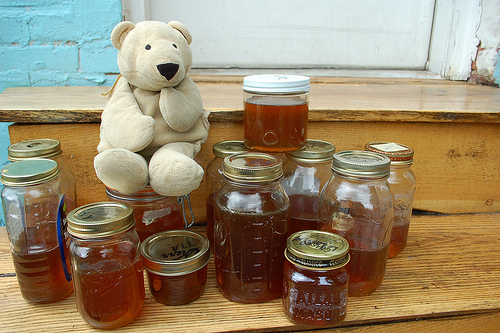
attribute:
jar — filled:
[279, 228, 349, 325]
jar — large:
[210, 150, 290, 302]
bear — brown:
[97, 15, 209, 193]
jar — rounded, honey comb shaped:
[1, 156, 73, 304]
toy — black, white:
[89, 17, 214, 201]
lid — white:
[243, 72, 313, 97]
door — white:
[195, 7, 438, 69]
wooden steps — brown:
[220, 61, 498, 243]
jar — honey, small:
[142, 224, 212, 304]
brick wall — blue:
[3, 2, 129, 104]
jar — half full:
[325, 147, 411, 273]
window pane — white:
[208, 29, 428, 69]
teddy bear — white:
[103, 20, 213, 195]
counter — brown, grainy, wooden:
[43, 105, 495, 296]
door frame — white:
[448, 0, 497, 74]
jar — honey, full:
[216, 152, 286, 303]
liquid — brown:
[391, 225, 407, 252]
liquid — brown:
[348, 250, 385, 294]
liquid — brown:
[218, 212, 285, 299]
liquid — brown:
[244, 97, 308, 149]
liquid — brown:
[76, 250, 141, 324]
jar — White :
[236, 69, 316, 162]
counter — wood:
[1, 209, 499, 327]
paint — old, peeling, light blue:
[3, 0, 123, 176]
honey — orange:
[246, 94, 310, 147]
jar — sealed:
[282, 229, 351, 329]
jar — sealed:
[215, 154, 279, 302]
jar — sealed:
[66, 208, 146, 329]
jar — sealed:
[148, 230, 210, 306]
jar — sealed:
[326, 152, 386, 296]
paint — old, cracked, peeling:
[2, 1, 495, 75]